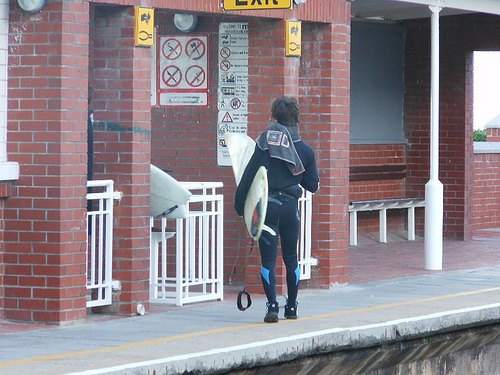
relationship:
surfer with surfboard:
[208, 78, 323, 326] [221, 125, 271, 243]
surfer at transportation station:
[208, 78, 323, 326] [2, 1, 498, 373]